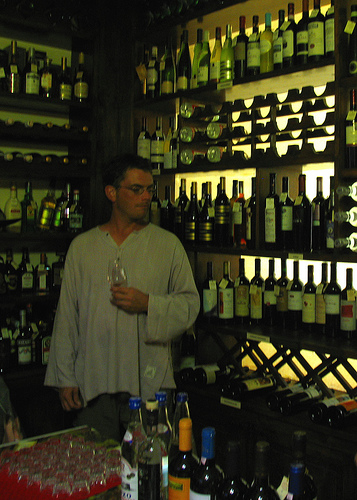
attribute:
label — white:
[279, 285, 310, 322]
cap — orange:
[179, 417, 192, 429]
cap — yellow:
[142, 397, 158, 410]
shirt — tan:
[55, 209, 188, 374]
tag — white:
[140, 362, 158, 384]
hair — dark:
[100, 152, 159, 192]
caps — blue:
[125, 389, 189, 406]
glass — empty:
[103, 254, 133, 302]